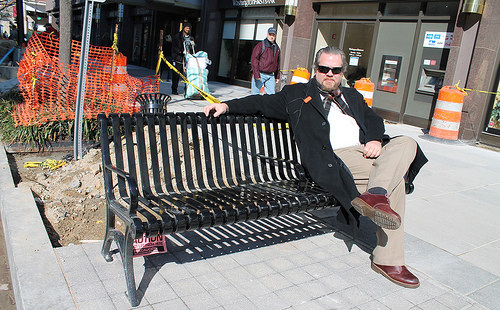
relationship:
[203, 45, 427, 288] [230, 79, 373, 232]
guy wearing coat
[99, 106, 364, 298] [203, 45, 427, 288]
bench under guy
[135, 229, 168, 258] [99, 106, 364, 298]
paper under bench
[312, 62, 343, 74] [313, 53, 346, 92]
glasses on face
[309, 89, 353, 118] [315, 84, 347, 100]
scarf around neck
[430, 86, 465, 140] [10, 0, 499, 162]
cone next to building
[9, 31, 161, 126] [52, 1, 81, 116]
barricade fencing around tree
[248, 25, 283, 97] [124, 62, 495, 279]
man on sidewalk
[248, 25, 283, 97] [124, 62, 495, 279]
man walking on sidewalk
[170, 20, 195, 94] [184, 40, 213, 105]
man pushing cart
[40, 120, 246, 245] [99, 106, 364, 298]
dirt behind bench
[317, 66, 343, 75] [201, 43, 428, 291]
glasses worn by guy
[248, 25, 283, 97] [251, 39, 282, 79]
man wearing coat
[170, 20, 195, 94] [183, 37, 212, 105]
man pushing luggage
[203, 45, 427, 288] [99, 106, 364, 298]
guy sitting on bench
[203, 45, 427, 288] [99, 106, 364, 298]
guy on bench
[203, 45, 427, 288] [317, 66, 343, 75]
guy wearing glasses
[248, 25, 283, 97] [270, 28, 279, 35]
man wearing cap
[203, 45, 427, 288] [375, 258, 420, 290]
guy has shoe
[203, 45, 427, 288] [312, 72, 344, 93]
guy with beard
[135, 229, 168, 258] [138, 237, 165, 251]
paper with writing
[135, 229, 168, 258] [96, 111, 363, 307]
paper on bench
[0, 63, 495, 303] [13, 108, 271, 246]
pavement has section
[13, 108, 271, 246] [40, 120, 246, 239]
section has dirt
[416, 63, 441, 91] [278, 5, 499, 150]
atm machine on wall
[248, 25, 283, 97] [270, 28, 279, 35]
man in cap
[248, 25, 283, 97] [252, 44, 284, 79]
man in coat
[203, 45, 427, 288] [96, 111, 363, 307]
guy sits on bench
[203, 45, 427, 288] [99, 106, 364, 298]
guy sits on bench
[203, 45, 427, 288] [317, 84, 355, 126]
guy with cravat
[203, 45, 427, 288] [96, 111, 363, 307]
guy on bench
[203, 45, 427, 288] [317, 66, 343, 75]
guy with glasses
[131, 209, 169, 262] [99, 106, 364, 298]
caution sign under bench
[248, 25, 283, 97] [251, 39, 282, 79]
man in coat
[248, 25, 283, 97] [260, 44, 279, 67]
man with backpack